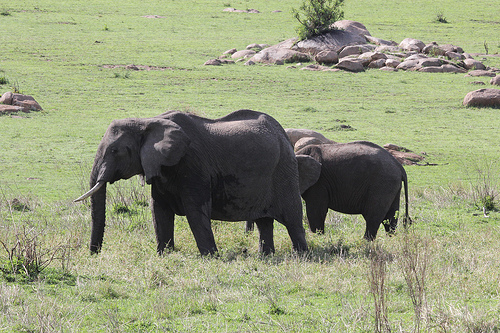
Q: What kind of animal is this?
A: Elephant.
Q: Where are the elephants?
A: Green field.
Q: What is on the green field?
A: Pile of rocks.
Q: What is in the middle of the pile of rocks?
A: Green plant.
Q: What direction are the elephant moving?
A: Left.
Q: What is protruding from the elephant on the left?
A: Tusks.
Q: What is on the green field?
A: Green grass.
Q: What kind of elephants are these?
A: Grey elephants.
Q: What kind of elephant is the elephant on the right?
A: Baby elephant.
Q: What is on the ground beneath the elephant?
A: Shadow.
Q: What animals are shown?
A: Elephants.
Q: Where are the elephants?
A: In the pasture.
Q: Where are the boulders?
A: Behind the elephants.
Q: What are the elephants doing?
A: Walking.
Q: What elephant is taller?
A: One on the left.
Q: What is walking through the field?
A: Elephants.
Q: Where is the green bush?
A: On the boulder.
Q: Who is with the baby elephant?
A: The mother.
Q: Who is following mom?
A: The baby elephant.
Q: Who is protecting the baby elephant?
A: The mother.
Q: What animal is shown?
A: Elephant.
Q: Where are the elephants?
A: IN the wild.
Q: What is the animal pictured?
A: Elephant.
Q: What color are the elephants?
A: Gray.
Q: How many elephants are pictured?
A: 2.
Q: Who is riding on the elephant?
A: Nobody.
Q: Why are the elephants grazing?
A: Hungry.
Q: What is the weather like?
A: Sunny.